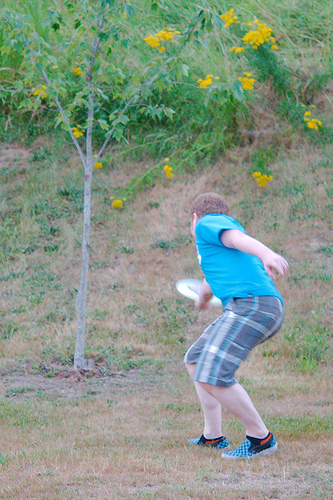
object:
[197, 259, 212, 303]
arm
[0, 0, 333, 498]
field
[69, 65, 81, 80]
flower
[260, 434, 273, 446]
stripe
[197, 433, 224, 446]
socks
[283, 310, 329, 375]
grass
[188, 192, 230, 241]
head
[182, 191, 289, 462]
boy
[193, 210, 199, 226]
ear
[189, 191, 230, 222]
hair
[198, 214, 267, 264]
arm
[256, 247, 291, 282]
hand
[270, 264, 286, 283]
fingers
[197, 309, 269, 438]
leg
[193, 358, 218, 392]
knee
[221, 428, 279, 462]
foot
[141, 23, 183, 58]
blossoms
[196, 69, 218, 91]
flower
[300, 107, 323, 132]
flower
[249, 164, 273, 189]
flower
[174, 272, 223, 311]
frisbee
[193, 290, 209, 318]
man's hand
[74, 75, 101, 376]
trunk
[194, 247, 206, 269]
emblem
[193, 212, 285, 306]
shirt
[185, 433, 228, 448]
shoe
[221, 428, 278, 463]
shoe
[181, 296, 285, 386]
shorts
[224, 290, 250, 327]
pocket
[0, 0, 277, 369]
tree